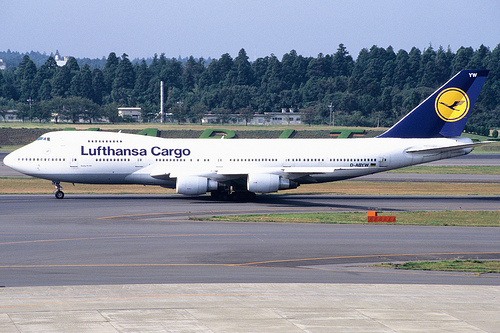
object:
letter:
[97, 146, 102, 156]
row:
[15, 158, 378, 163]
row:
[88, 140, 123, 143]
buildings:
[0, 80, 311, 125]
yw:
[469, 73, 478, 78]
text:
[81, 145, 147, 156]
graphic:
[375, 69, 490, 139]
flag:
[370, 163, 376, 167]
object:
[367, 210, 397, 222]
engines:
[176, 173, 301, 196]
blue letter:
[124, 149, 131, 156]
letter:
[81, 145, 89, 155]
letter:
[151, 146, 161, 156]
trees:
[0, 43, 500, 128]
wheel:
[55, 189, 65, 199]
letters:
[81, 146, 191, 159]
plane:
[2, 70, 489, 197]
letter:
[88, 146, 146, 156]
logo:
[434, 87, 472, 122]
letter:
[88, 148, 96, 155]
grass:
[184, 210, 500, 227]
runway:
[0, 195, 500, 286]